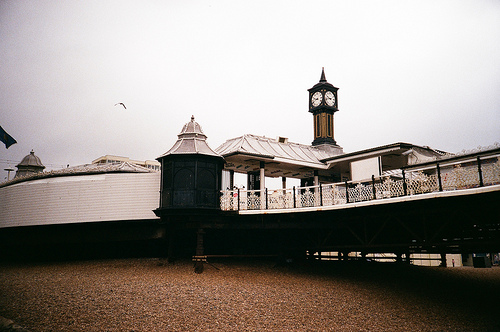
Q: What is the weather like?
A: It is clear.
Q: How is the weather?
A: It is clear.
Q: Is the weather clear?
A: Yes, it is clear.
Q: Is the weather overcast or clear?
A: It is clear.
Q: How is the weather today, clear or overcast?
A: It is clear.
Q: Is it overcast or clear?
A: It is clear.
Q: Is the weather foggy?
A: No, it is clear.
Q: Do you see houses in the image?
A: No, there are no houses.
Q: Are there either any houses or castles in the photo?
A: No, there are no houses or castles.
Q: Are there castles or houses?
A: No, there are no houses or castles.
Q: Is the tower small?
A: Yes, the tower is small.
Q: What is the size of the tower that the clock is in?
A: The tower is small.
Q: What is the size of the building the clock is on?
A: The tower is small.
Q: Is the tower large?
A: No, the tower is small.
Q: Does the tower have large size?
A: No, the tower is small.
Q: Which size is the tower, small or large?
A: The tower is small.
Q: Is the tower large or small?
A: The tower is small.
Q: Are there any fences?
A: Yes, there is a fence.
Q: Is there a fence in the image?
A: Yes, there is a fence.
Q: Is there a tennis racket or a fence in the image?
A: Yes, there is a fence.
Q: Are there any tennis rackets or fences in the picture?
A: Yes, there is a fence.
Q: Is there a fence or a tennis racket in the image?
A: Yes, there is a fence.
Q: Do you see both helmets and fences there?
A: No, there is a fence but no helmets.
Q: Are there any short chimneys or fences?
A: Yes, there is a short fence.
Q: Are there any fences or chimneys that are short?
A: Yes, the fence is short.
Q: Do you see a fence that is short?
A: Yes, there is a short fence.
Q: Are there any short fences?
A: Yes, there is a short fence.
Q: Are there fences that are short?
A: Yes, there is a fence that is short.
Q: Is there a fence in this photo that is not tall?
A: Yes, there is a short fence.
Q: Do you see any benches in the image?
A: No, there are no benches.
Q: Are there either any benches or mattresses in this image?
A: No, there are no benches or mattresses.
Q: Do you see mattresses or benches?
A: No, there are no benches or mattresses.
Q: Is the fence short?
A: Yes, the fence is short.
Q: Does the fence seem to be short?
A: Yes, the fence is short.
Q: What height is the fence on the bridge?
A: The fence is short.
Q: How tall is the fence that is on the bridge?
A: The fence is short.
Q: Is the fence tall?
A: No, the fence is short.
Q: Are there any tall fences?
A: No, there is a fence but it is short.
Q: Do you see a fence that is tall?
A: No, there is a fence but it is short.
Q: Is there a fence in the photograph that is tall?
A: No, there is a fence but it is short.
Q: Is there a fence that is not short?
A: No, there is a fence but it is short.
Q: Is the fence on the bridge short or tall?
A: The fence is short.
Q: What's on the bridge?
A: The fence is on the bridge.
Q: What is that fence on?
A: The fence is on the bridge.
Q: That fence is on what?
A: The fence is on the bridge.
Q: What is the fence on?
A: The fence is on the bridge.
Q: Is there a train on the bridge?
A: No, there is a fence on the bridge.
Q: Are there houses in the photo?
A: No, there are no houses.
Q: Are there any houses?
A: No, there are no houses.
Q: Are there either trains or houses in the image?
A: No, there are no houses or trains.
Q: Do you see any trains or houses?
A: No, there are no houses or trains.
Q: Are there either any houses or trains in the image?
A: No, there are no houses or trains.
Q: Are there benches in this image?
A: No, there are no benches.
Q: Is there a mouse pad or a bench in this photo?
A: No, there are no benches or mouse pads.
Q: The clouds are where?
A: The clouds are in the sky.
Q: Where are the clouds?
A: The clouds are in the sky.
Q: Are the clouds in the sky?
A: Yes, the clouds are in the sky.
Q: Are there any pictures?
A: No, there are no pictures.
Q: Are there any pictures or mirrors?
A: No, there are no pictures or mirrors.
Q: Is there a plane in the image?
A: No, there are no airplanes.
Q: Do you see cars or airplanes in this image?
A: No, there are no airplanes or cars.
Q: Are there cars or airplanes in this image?
A: No, there are no airplanes or cars.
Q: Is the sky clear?
A: Yes, the sky is clear.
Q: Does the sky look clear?
A: Yes, the sky is clear.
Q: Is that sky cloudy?
A: No, the sky is clear.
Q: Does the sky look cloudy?
A: No, the sky is clear.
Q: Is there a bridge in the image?
A: Yes, there is a bridge.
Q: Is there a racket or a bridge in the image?
A: Yes, there is a bridge.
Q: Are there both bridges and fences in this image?
A: Yes, there are both a bridge and a fence.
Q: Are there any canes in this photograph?
A: No, there are no canes.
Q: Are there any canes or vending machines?
A: No, there are no canes or vending machines.